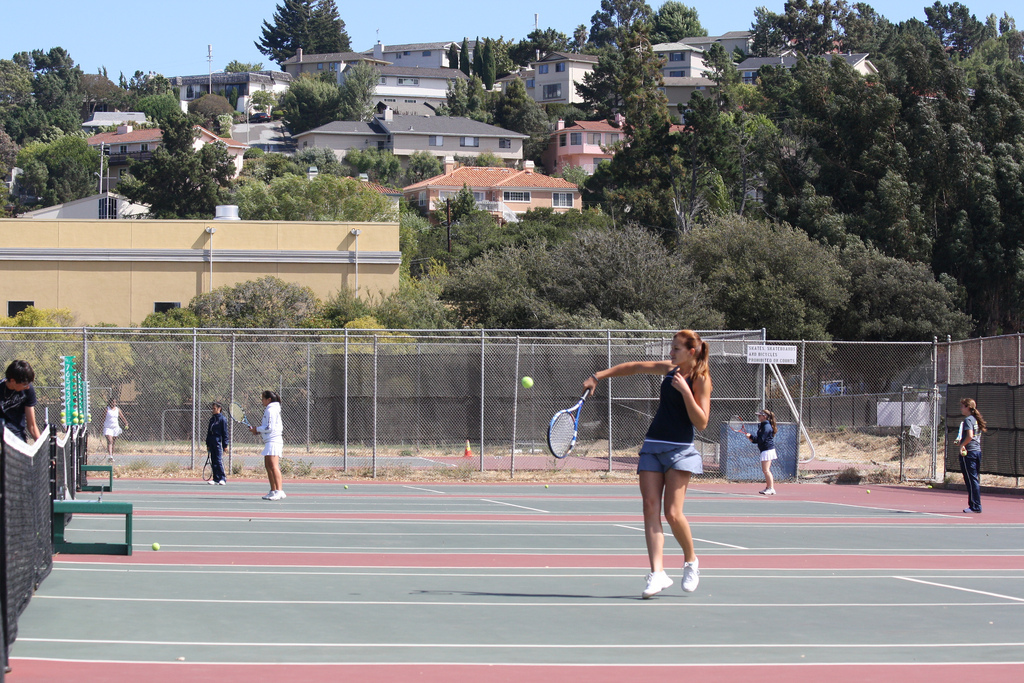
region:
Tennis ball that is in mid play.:
[521, 375, 535, 389]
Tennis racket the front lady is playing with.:
[546, 388, 595, 455]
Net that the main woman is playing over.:
[0, 426, 54, 668]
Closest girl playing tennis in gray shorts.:
[585, 331, 713, 595]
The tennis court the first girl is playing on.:
[6, 562, 1022, 665]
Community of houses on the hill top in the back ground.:
[81, 22, 884, 228]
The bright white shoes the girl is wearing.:
[644, 557, 703, 595]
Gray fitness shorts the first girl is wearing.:
[634, 437, 705, 472]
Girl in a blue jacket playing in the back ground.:
[730, 407, 778, 494]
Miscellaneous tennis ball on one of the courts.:
[151, 540, 162, 548]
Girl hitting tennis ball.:
[514, 321, 714, 596]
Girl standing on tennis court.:
[946, 390, 979, 505]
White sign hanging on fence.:
[735, 333, 790, 357]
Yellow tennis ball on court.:
[143, 532, 153, 539]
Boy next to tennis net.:
[0, 346, 36, 438]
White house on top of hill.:
[471, 33, 599, 95]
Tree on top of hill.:
[245, 0, 344, 61]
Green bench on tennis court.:
[43, 492, 127, 549]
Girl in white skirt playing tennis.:
[724, 403, 779, 493]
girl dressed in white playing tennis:
[240, 386, 291, 501]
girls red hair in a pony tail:
[672, 326, 712, 396]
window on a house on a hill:
[427, 133, 441, 146]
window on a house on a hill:
[457, 137, 481, 147]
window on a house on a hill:
[496, 134, 513, 148]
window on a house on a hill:
[503, 188, 529, 202]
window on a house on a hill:
[550, 188, 576, 205]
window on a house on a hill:
[565, 130, 585, 144]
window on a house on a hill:
[581, 130, 597, 143]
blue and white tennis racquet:
[534, 379, 601, 466]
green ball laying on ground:
[136, 527, 175, 563]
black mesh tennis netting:
[0, 433, 51, 611]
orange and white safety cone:
[451, 423, 483, 466]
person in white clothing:
[245, 372, 300, 513]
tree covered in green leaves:
[736, 132, 1005, 316]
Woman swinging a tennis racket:
[544, 325, 716, 597]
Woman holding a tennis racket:
[223, 381, 288, 499]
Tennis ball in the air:
[513, 368, 534, 391]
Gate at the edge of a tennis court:
[0, 321, 1012, 489]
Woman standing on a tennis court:
[945, 390, 993, 515]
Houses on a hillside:
[5, 21, 885, 222]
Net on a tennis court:
[0, 400, 59, 663]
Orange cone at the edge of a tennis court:
[459, 433, 476, 462]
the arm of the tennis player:
[593, 354, 671, 389]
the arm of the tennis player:
[681, 370, 711, 425]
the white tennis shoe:
[645, 566, 674, 598]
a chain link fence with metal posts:
[78, 318, 203, 483]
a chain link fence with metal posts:
[322, 313, 504, 506]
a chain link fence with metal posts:
[468, 312, 642, 497]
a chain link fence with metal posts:
[596, 318, 777, 478]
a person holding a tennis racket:
[214, 380, 326, 524]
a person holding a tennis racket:
[720, 397, 791, 519]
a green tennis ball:
[503, 363, 546, 390]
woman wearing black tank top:
[582, 323, 732, 599]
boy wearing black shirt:
[3, 348, 55, 459]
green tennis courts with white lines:
[22, 449, 1022, 666]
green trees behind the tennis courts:
[13, 14, 1022, 335]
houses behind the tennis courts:
[10, 14, 887, 328]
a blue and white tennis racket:
[541, 387, 590, 460]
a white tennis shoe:
[645, 569, 674, 593]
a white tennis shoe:
[677, 558, 700, 591]